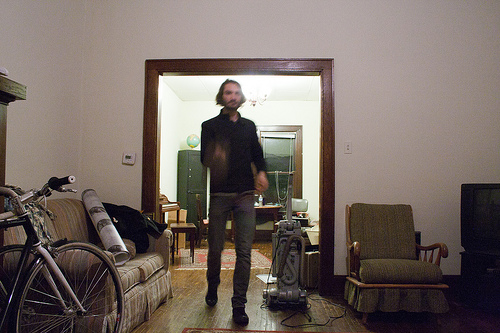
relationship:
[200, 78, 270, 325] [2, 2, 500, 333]
man in living room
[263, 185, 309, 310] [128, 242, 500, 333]
vacuum on floor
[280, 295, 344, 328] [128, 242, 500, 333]
cord on floor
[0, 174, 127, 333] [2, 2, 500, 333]
bike in living room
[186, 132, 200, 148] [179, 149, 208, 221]
globe on cabinet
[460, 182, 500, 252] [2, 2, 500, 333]
television in living room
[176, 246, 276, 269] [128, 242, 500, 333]
rug on floor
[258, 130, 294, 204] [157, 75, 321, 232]
window on wall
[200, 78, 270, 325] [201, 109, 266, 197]
man wearing sweater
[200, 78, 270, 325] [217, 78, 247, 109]
man has hair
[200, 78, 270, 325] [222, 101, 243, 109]
man has beard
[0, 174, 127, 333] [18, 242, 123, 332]
bike has tire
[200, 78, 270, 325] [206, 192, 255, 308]
man wearing jeans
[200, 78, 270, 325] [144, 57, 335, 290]
man in doorway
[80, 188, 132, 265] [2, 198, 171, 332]
poster on couch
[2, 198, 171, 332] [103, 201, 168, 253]
couch has jacket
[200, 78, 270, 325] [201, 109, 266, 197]
man has sweater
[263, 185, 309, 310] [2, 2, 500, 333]
vacuum in living room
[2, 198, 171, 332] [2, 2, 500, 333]
couch in living room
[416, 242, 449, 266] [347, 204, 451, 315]
armrest on chair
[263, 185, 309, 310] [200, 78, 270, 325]
vacuum to right of man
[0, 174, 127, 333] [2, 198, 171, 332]
bike next to couch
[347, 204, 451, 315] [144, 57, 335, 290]
chair to right of doorway